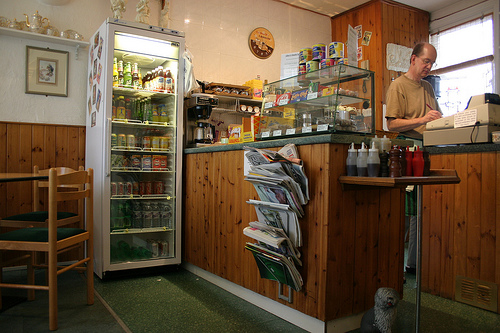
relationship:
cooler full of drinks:
[78, 13, 188, 273] [111, 55, 176, 261]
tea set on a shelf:
[17, 10, 84, 42] [6, 23, 95, 48]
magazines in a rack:
[243, 144, 310, 292] [232, 145, 312, 306]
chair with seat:
[22, 175, 100, 320] [6, 221, 84, 246]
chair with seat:
[0, 152, 89, 291] [8, 204, 72, 228]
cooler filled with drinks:
[80, 16, 182, 281] [114, 57, 175, 93]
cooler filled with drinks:
[80, 16, 182, 281] [112, 92, 171, 124]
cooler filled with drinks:
[80, 16, 182, 281] [109, 130, 171, 152]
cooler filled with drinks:
[80, 16, 182, 281] [112, 175, 172, 195]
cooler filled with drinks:
[80, 16, 182, 281] [112, 203, 171, 223]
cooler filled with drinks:
[80, 16, 182, 281] [113, 236, 168, 259]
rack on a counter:
[243, 150, 312, 305] [188, 129, 404, 330]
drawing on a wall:
[25, 45, 69, 97] [6, 1, 335, 139]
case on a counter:
[256, 62, 373, 134] [188, 129, 404, 330]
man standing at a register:
[387, 40, 444, 273] [420, 91, 498, 147]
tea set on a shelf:
[0, 10, 84, 42] [0, 28, 90, 55]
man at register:
[387, 40, 444, 273] [420, 91, 498, 147]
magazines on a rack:
[243, 144, 310, 292] [212, 132, 308, 286]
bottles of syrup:
[341, 143, 383, 178] [344, 161, 381, 175]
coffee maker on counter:
[184, 94, 220, 149] [184, 143, 246, 294]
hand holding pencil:
[419, 110, 444, 122] [422, 100, 436, 112]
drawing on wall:
[27, 46, 69, 95] [3, 38, 86, 163]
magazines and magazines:
[243, 144, 310, 292] [245, 145, 307, 296]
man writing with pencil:
[387, 37, 437, 121] [423, 96, 433, 116]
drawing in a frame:
[25, 45, 69, 97] [19, 86, 70, 102]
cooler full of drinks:
[80, 16, 182, 281] [111, 55, 176, 261]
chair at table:
[0, 168, 94, 332] [7, 168, 30, 184]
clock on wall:
[246, 26, 275, 60] [194, 6, 248, 83]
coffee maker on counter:
[177, 83, 223, 148] [188, 111, 419, 326]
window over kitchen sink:
[427, 14, 494, 116] [415, 14, 498, 136]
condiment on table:
[366, 141, 383, 178] [339, 168, 461, 330]